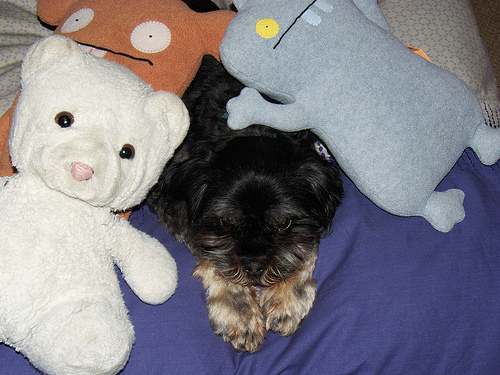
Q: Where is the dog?
A: In the middle.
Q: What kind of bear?
A: Teddy.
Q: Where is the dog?
A: Under stuffed animals.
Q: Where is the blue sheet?
A: On the bed.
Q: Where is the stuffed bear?
A: On the left.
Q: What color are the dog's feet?
A: Brown.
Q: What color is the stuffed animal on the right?
A: Grey.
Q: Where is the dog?
A: On the bed.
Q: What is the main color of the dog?
A: Black.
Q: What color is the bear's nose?
A: Pink.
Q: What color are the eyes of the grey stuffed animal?
A: Yellow.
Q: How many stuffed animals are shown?
A: 3.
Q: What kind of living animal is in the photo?
A: Dog.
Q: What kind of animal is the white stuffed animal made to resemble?
A: Teddy bear.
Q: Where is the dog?
A: Purple sheet.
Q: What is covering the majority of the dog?
A: Stuffed animals.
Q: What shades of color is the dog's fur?
A: Black and tan.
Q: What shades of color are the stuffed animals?
A: Coral, pastel blue and white.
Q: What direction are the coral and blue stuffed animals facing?
A: Facing the ceiling.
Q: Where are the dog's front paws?
A: In front of the dog.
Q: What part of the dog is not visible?
A: Hind legs.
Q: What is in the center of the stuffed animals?
A: Dog.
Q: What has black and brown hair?
A: Dog.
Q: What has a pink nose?
A: Teddy bear.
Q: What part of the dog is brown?
A: Paws.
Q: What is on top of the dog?
A: Stuffed toys.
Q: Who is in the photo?
A: Nobody.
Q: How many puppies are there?
A: One.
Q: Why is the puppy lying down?
A: To rest.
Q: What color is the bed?
A: Blue.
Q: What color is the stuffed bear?
A: White.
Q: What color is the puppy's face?
A: Black.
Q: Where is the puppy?
A: On the bed.